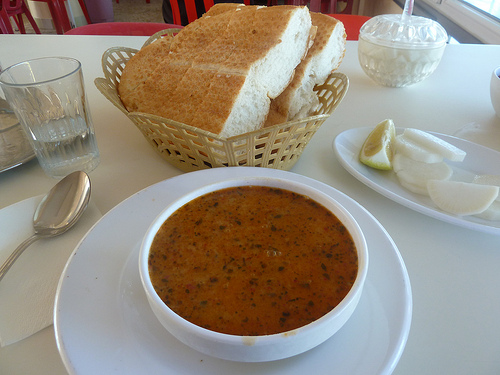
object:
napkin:
[0, 189, 105, 350]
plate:
[53, 164, 415, 373]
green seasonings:
[221, 248, 266, 278]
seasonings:
[222, 262, 249, 274]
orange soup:
[147, 185, 359, 336]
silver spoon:
[0, 170, 91, 281]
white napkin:
[2, 200, 52, 330]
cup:
[0, 56, 102, 177]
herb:
[209, 271, 218, 283]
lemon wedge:
[357, 112, 396, 186]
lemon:
[356, 117, 396, 169]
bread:
[115, 1, 347, 167]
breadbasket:
[93, 27, 349, 179]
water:
[25, 118, 96, 174]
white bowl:
[133, 171, 370, 361]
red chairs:
[1, 2, 426, 36]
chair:
[53, 2, 233, 38]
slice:
[353, 113, 403, 171]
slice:
[419, 173, 499, 218]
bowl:
[136, 174, 371, 362]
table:
[0, 33, 498, 373]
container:
[356, 0, 450, 88]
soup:
[147, 186, 358, 337]